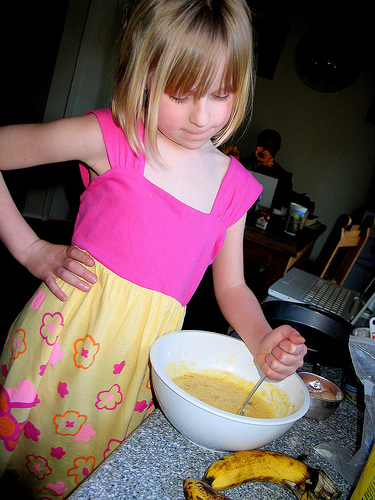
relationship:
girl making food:
[1, 1, 308, 500] [168, 363, 279, 430]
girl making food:
[1, 1, 308, 500] [175, 445, 343, 499]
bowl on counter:
[144, 322, 313, 454] [58, 324, 374, 498]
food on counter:
[175, 445, 343, 499] [58, 324, 374, 498]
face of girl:
[150, 32, 244, 155] [1, 1, 308, 500]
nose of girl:
[189, 103, 214, 130] [1, 1, 308, 500]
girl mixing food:
[1, 1, 308, 500] [168, 363, 279, 430]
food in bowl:
[168, 363, 279, 430] [144, 322, 313, 454]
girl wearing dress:
[1, 1, 308, 500] [2, 106, 263, 498]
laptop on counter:
[266, 259, 374, 329] [58, 324, 374, 498]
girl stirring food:
[1, 1, 308, 500] [168, 363, 279, 430]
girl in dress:
[1, 1, 308, 500] [2, 106, 263, 498]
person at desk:
[244, 124, 293, 194] [185, 185, 326, 339]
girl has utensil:
[1, 1, 308, 500] [235, 366, 272, 417]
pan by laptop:
[255, 293, 358, 374] [266, 259, 374, 329]